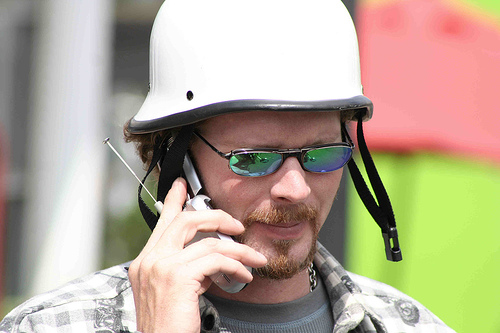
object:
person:
[1, 1, 458, 333]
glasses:
[193, 120, 353, 177]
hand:
[127, 177, 268, 333]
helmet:
[121, 0, 372, 137]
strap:
[341, 116, 403, 262]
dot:
[187, 91, 194, 101]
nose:
[271, 156, 312, 205]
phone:
[102, 136, 253, 294]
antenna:
[102, 136, 157, 204]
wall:
[352, 0, 499, 333]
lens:
[303, 145, 354, 173]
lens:
[230, 151, 284, 177]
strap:
[138, 123, 196, 232]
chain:
[306, 263, 318, 292]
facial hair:
[235, 202, 320, 280]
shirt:
[0, 238, 457, 332]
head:
[155, 107, 344, 281]